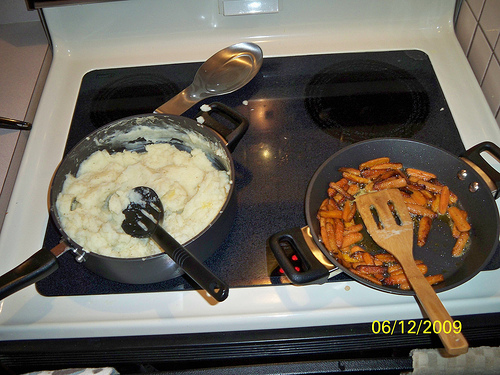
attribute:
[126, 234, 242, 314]
plastic spoon — black